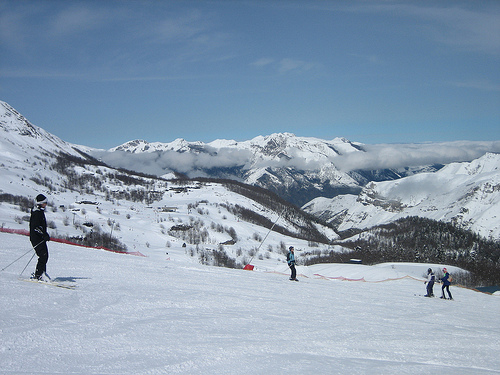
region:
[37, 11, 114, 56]
white clouds in blue sky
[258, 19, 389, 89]
white clouds in blue sky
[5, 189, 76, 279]
skier on snowy hill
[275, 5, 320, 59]
white clouds in blue sky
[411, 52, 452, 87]
white clouds in blue sky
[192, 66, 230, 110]
white clouds in blue sky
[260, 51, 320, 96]
white clouds in blue sky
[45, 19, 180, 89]
white clouds in blue sky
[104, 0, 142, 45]
white clouds in blue sky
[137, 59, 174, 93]
white clouds in blue sky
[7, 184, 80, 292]
a person wearing black skiing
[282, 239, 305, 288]
a person on a ski slope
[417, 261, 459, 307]
two people on a ski slope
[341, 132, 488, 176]
a cloud in the mountains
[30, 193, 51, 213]
a head of a person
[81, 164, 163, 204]
trees on the side of a mountain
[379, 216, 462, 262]
a forest of trees on a hill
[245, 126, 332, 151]
the top of a mountain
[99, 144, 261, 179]
a cloud in the mountains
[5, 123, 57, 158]
the snow on the side of a mountain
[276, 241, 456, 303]
People out snow sking on mountain.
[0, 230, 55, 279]
Person holding two ski poles.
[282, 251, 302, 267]
Man dressed in blue and black jacket.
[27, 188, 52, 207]
Person wearing wool cap on head.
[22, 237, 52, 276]
Person wearing black pants.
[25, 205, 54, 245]
Person dressed in black jacket.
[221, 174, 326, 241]
Tree covered mountain slope.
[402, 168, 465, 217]
Snow covered mountain slope.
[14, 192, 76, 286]
skier in snow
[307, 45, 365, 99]
white clouds in blue sky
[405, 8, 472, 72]
white clouds in blue sky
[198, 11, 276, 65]
white clouds in blue sky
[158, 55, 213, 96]
white clouds in blue sky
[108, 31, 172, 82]
white clouds in blue sky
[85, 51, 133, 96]
white clouds in blue sky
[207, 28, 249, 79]
white clouds in blue sky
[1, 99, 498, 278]
snow covered mountains in the background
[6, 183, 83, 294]
skier dressed in black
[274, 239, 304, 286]
skier wearing a blue coat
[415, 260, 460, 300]
two people on the ski slope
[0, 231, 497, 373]
white snow packed on the ski slope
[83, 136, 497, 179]
clouds in front of the mountains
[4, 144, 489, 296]
lots of trees on the mountains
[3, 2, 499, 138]
beautiful blue sky with a few clouds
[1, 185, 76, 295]
skier is holding two poles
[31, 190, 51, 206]
white and black winter hat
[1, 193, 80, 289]
Guy in black ski clothes on the slope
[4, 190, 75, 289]
Skiier with black ski suit and black beanie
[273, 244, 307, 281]
Guy in light and dark blue ski attire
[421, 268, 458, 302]
Two people on the snowy slopes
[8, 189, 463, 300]
Four people skiing on the slopes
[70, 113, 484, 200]
Snow covered mountain with low lying clouds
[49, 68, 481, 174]
Blue skies over a white snow covered mountain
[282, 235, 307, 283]
Man in blue skiing down the slope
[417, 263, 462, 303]
Two people standing in their skis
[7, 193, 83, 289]
Man in black and white on his skis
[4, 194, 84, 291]
man skiing down hillside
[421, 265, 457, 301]
two skiers on a hillside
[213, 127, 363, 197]
snow covered mountail peaks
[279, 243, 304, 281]
man skiing down hill